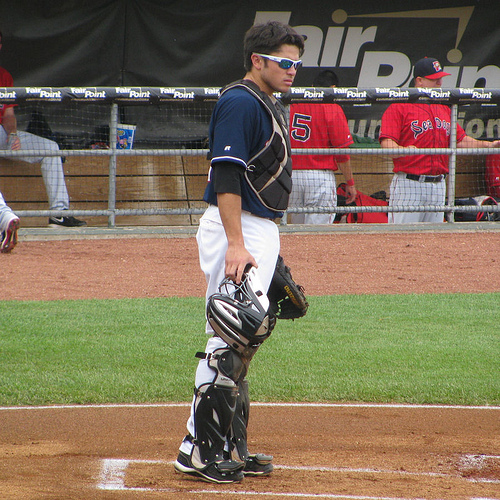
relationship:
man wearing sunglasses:
[175, 14, 307, 483] [247, 46, 307, 73]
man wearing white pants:
[175, 14, 307, 483] [179, 202, 283, 460]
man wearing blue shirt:
[175, 14, 307, 483] [192, 82, 301, 221]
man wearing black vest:
[175, 14, 307, 483] [220, 81, 301, 212]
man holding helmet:
[175, 14, 307, 483] [202, 267, 283, 355]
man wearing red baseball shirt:
[375, 50, 484, 232] [376, 100, 467, 179]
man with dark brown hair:
[175, 14, 307, 483] [235, 20, 309, 67]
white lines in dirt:
[91, 444, 167, 499] [1, 404, 499, 494]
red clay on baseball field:
[2, 230, 497, 300] [4, 235, 484, 498]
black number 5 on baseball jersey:
[288, 113, 316, 145] [286, 98, 356, 172]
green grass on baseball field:
[0, 299, 500, 402] [4, 235, 484, 498]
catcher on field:
[175, 14, 307, 483] [4, 235, 484, 498]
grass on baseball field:
[0, 299, 500, 402] [4, 235, 484, 498]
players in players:
[0, 68, 499, 216] [0, 56, 500, 250]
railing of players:
[2, 92, 498, 223] [0, 56, 500, 250]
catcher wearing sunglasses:
[175, 14, 307, 483] [247, 46, 307, 73]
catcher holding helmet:
[156, 16, 315, 484] [202, 267, 283, 355]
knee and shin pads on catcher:
[197, 347, 245, 483] [156, 16, 315, 484]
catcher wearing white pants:
[156, 16, 315, 484] [179, 202, 283, 460]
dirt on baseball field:
[1, 404, 499, 494] [4, 235, 484, 498]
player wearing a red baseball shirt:
[375, 50, 484, 232] [376, 100, 467, 179]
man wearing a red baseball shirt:
[378, 57, 500, 224] [376, 100, 467, 179]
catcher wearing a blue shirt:
[156, 16, 315, 484] [192, 82, 301, 221]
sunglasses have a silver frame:
[247, 46, 307, 73] [249, 49, 282, 65]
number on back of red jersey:
[288, 113, 316, 145] [286, 98, 356, 172]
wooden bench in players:
[6, 140, 207, 220] [0, 56, 500, 250]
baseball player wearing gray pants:
[0, 63, 92, 236] [2, 127, 79, 213]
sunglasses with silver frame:
[247, 46, 307, 73] [249, 49, 282, 65]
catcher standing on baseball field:
[156, 16, 315, 484] [4, 235, 484, 498]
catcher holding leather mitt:
[156, 16, 315, 484] [269, 256, 316, 322]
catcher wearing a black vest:
[156, 16, 315, 484] [220, 81, 301, 212]